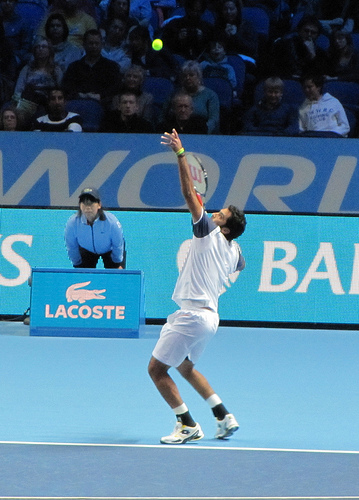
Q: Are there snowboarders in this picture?
A: No, there are no snowboarders.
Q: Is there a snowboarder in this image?
A: No, there are no snowboarders.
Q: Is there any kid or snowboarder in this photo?
A: No, there are no snowboarders or children.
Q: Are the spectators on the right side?
A: Yes, the spectators are on the right of the image.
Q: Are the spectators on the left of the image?
A: No, the spectators are on the right of the image.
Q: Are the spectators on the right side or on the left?
A: The spectators are on the right of the image.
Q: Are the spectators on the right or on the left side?
A: The spectators are on the right of the image.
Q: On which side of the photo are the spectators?
A: The spectators are on the right of the image.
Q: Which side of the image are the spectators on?
A: The spectators are on the right of the image.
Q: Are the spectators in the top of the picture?
A: Yes, the spectators are in the top of the image.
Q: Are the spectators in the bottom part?
A: No, the spectators are in the top of the image.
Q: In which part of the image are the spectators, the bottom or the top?
A: The spectators are in the top of the image.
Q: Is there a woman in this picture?
A: Yes, there is a woman.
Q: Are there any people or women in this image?
A: Yes, there is a woman.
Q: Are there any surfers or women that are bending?
A: Yes, the woman is bending.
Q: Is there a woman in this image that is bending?
A: Yes, there is a woman that is bending.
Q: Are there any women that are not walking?
A: Yes, there is a woman that is bending.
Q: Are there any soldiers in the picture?
A: No, there are no soldiers.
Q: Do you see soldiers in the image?
A: No, there are no soldiers.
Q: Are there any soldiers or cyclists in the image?
A: No, there are no soldiers or cyclists.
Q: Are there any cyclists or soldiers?
A: No, there are no soldiers or cyclists.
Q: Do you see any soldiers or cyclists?
A: No, there are no soldiers or cyclists.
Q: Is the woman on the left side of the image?
A: Yes, the woman is on the left of the image.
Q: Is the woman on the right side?
A: No, the woman is on the left of the image.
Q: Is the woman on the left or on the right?
A: The woman is on the left of the image.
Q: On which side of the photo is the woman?
A: The woman is on the left of the image.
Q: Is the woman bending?
A: Yes, the woman is bending.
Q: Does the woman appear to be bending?
A: Yes, the woman is bending.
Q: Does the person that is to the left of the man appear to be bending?
A: Yes, the woman is bending.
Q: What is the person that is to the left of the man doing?
A: The woman is bending.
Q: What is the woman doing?
A: The woman is bending.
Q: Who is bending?
A: The woman is bending.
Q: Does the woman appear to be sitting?
A: No, the woman is bending.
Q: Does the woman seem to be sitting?
A: No, the woman is bending.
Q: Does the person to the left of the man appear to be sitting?
A: No, the woman is bending.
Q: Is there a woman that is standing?
A: No, there is a woman but she is bending.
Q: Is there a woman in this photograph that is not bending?
A: No, there is a woman but she is bending.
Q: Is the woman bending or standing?
A: The woman is bending.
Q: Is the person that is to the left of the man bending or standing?
A: The woman is bending.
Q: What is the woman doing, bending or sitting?
A: The woman is bending.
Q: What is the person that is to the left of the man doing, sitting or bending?
A: The woman is bending.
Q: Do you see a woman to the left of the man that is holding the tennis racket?
A: Yes, there is a woman to the left of the man.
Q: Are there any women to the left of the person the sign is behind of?
A: Yes, there is a woman to the left of the man.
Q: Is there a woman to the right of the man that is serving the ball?
A: No, the woman is to the left of the man.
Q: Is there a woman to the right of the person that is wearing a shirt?
A: No, the woman is to the left of the man.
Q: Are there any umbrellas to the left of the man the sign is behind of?
A: No, there is a woman to the left of the man.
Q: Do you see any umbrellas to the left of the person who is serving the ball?
A: No, there is a woman to the left of the man.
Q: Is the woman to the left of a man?
A: Yes, the woman is to the left of a man.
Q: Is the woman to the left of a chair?
A: No, the woman is to the left of a man.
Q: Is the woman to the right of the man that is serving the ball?
A: No, the woman is to the left of the man.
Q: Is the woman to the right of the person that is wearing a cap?
A: No, the woman is to the left of the man.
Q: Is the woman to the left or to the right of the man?
A: The woman is to the left of the man.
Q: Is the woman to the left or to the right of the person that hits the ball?
A: The woman is to the left of the man.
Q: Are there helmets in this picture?
A: No, there are no helmets.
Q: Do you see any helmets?
A: No, there are no helmets.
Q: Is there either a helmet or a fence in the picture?
A: No, there are no helmets or fences.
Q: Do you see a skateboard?
A: No, there are no skateboards.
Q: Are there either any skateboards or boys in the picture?
A: No, there are no skateboards or boys.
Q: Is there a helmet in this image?
A: No, there are no helmets.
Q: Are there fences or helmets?
A: No, there are no helmets or fences.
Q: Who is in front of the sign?
A: The man is in front of the sign.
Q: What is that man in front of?
A: The man is in front of the sign.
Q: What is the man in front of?
A: The man is in front of the sign.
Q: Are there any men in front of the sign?
A: Yes, there is a man in front of the sign.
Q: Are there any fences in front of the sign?
A: No, there is a man in front of the sign.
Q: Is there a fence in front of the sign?
A: No, there is a man in front of the sign.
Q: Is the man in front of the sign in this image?
A: Yes, the man is in front of the sign.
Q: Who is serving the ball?
A: The man is serving the ball.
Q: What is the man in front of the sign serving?
A: The man is serving the ball.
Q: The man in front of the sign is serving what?
A: The man is serving the ball.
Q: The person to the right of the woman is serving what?
A: The man is serving the ball.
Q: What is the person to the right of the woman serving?
A: The man is serving the ball.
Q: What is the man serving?
A: The man is serving the ball.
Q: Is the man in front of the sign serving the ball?
A: Yes, the man is serving the ball.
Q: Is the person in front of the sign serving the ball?
A: Yes, the man is serving the ball.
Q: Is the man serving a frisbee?
A: No, the man is serving the ball.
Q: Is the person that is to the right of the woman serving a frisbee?
A: No, the man is serving the ball.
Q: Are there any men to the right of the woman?
A: Yes, there is a man to the right of the woman.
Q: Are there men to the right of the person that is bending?
A: Yes, there is a man to the right of the woman.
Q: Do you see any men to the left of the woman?
A: No, the man is to the right of the woman.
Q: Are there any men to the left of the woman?
A: No, the man is to the right of the woman.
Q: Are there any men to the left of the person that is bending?
A: No, the man is to the right of the woman.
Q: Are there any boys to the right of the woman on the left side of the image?
A: No, there is a man to the right of the woman.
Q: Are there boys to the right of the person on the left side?
A: No, there is a man to the right of the woman.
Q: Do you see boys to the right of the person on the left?
A: No, there is a man to the right of the woman.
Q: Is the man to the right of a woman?
A: Yes, the man is to the right of a woman.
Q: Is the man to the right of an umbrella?
A: No, the man is to the right of a woman.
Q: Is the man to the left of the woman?
A: No, the man is to the right of the woman.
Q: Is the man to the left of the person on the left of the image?
A: No, the man is to the right of the woman.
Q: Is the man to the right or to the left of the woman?
A: The man is to the right of the woman.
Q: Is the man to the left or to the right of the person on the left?
A: The man is to the right of the woman.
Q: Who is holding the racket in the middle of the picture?
A: The man is holding the tennis racket.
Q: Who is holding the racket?
A: The man is holding the tennis racket.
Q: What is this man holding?
A: The man is holding the racket.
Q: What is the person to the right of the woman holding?
A: The man is holding the racket.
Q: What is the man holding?
A: The man is holding the racket.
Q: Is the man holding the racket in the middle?
A: Yes, the man is holding the racket.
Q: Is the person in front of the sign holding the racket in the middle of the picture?
A: Yes, the man is holding the racket.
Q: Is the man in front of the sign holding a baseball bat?
A: No, the man is holding the racket.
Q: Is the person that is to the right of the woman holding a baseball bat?
A: No, the man is holding the racket.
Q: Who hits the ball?
A: The man hits the ball.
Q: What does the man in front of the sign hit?
A: The man hits the ball.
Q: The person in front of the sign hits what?
A: The man hits the ball.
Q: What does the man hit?
A: The man hits the ball.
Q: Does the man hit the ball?
A: Yes, the man hits the ball.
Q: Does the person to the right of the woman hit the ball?
A: Yes, the man hits the ball.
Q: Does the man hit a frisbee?
A: No, the man hits the ball.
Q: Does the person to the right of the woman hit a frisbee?
A: No, the man hits the ball.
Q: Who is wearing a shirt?
A: The man is wearing a shirt.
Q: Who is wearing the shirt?
A: The man is wearing a shirt.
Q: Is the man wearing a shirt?
A: Yes, the man is wearing a shirt.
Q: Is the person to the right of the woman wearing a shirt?
A: Yes, the man is wearing a shirt.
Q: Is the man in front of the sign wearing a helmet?
A: No, the man is wearing a shirt.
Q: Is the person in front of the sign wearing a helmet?
A: No, the man is wearing a shirt.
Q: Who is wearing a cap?
A: The man is wearing a cap.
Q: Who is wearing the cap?
A: The man is wearing a cap.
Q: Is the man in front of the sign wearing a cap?
A: Yes, the man is wearing a cap.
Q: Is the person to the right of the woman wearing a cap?
A: Yes, the man is wearing a cap.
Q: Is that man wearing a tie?
A: No, the man is wearing a cap.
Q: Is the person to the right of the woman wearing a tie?
A: No, the man is wearing a cap.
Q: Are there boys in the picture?
A: No, there are no boys.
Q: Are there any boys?
A: No, there are no boys.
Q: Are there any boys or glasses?
A: No, there are no boys or glasses.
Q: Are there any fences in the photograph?
A: No, there are no fences.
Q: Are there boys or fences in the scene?
A: No, there are no fences or boys.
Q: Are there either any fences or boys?
A: No, there are no fences or boys.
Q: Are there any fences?
A: No, there are no fences.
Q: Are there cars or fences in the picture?
A: No, there are no fences or cars.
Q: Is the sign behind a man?
A: Yes, the sign is behind a man.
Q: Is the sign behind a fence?
A: No, the sign is behind a man.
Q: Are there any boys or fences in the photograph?
A: No, there are no boys or fences.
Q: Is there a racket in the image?
A: Yes, there is a racket.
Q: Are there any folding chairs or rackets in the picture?
A: Yes, there is a racket.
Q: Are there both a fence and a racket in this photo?
A: No, there is a racket but no fences.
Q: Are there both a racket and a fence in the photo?
A: No, there is a racket but no fences.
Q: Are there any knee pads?
A: No, there are no knee pads.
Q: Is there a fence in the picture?
A: No, there are no fences.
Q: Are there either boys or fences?
A: No, there are no fences or boys.